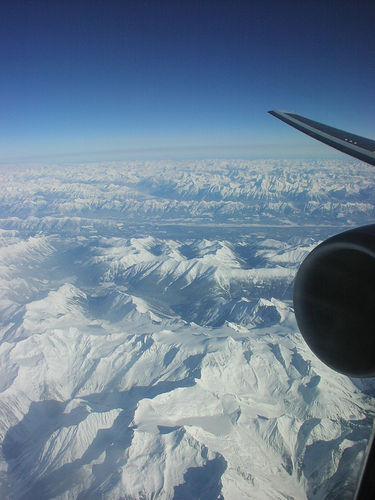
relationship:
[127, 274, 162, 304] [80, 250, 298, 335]
dip on mountain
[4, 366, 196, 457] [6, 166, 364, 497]
dark shadows on mountains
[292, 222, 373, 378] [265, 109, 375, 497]
engine on airplane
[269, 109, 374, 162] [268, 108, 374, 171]
stripe on wing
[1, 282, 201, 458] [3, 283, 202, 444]
snow on mountain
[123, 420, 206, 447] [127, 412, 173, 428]
mountain peak covered in snow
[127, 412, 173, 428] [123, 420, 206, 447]
snow covering mountain peak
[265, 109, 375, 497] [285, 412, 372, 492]
airplane casting shadow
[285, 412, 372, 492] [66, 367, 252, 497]
shadow over mountain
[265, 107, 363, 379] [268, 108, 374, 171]
airplane has wing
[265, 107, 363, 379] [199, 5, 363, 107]
airplane in sky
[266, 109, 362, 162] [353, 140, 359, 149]
plane's wing has white mark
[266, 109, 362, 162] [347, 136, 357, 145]
plane's wing has white mark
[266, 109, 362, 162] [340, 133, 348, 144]
plane's wing has white mark